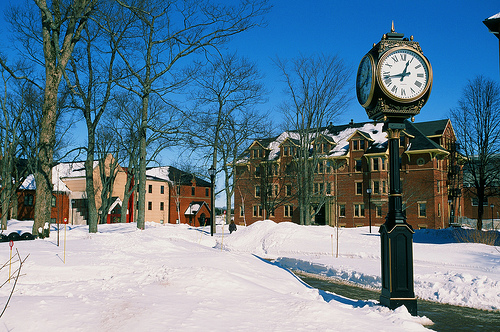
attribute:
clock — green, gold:
[355, 20, 435, 316]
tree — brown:
[1, 2, 100, 240]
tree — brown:
[438, 74, 499, 235]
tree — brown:
[258, 44, 360, 224]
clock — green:
[373, 48, 433, 97]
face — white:
[388, 61, 408, 86]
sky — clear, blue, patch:
[5, 7, 491, 184]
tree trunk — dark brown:
[29, 115, 60, 219]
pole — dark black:
[374, 119, 424, 322]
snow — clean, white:
[242, 262, 312, 324]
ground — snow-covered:
[2, 218, 496, 329]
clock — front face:
[364, 34, 439, 114]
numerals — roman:
[398, 82, 411, 98]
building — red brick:
[172, 173, 212, 221]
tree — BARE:
[4, 3, 93, 236]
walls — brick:
[292, 141, 449, 228]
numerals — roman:
[380, 49, 429, 92]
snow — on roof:
[270, 124, 385, 155]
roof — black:
[148, 166, 211, 189]